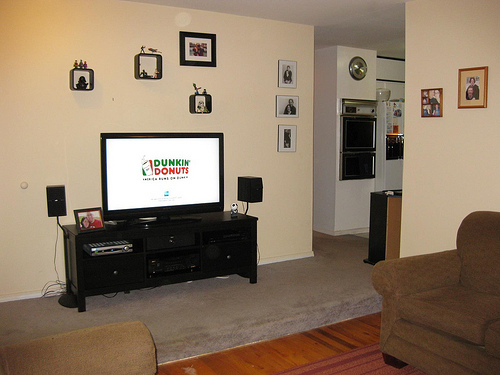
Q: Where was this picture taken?
A: A living room.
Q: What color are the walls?
A: Cream.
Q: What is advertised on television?
A: Dunkin Donuts.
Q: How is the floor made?
A: Of wood.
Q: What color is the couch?
A: Brown.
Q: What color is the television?
A: Black.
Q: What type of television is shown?
A: Flat screen.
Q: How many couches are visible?
A: Two.